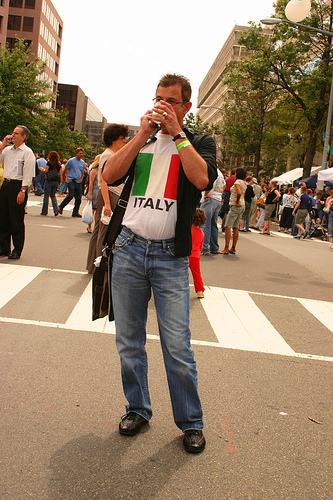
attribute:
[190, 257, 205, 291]
pants — red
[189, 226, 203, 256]
shirt — red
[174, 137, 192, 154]
armband — green, neon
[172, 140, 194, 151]
wrist band — fluorescent, green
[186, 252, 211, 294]
pants — red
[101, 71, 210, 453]
man — drinking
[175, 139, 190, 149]
wrist band — bright green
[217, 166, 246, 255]
woman — standing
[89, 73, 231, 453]
man — young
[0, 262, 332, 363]
white lines — painted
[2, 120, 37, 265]
man — talking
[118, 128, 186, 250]
shirt — white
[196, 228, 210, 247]
shirt — red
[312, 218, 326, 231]
child — sitting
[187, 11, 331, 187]
buildings — tall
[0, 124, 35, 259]
man — talking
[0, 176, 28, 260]
pants — black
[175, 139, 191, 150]
bracelet — green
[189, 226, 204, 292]
clothes — red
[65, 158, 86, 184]
shirt — blue